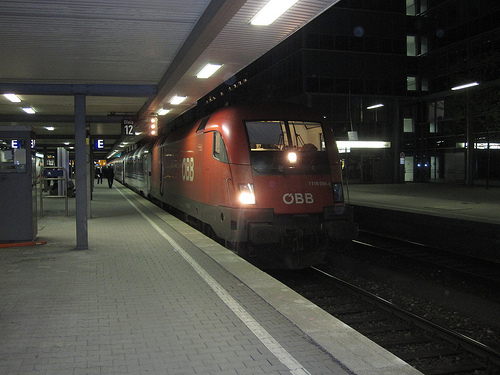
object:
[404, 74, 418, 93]
windows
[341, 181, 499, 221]
ground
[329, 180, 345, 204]
headlight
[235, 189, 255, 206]
light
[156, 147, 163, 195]
door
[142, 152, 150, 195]
door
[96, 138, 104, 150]
light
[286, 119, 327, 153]
window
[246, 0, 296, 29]
light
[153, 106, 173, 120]
light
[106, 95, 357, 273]
subway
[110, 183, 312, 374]
line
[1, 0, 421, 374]
platform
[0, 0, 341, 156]
ceiling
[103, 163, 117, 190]
people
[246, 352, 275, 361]
bricks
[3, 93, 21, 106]
light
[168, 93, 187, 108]
light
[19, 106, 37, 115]
light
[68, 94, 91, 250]
pole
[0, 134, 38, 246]
partition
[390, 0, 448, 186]
building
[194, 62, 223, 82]
light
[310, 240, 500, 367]
track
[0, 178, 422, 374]
floor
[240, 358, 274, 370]
brick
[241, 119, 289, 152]
windows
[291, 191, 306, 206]
white letter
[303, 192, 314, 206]
white letter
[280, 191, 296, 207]
white letter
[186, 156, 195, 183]
white letter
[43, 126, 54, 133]
light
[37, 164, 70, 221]
gate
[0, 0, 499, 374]
station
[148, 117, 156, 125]
light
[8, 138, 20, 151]
light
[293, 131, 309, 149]
wiper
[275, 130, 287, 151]
wiper